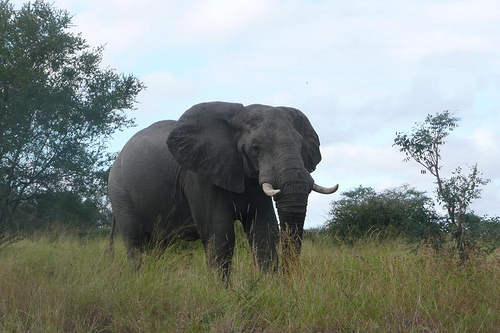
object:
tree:
[391, 108, 475, 265]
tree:
[0, 0, 149, 250]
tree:
[465, 212, 499, 255]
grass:
[412, 261, 477, 327]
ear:
[164, 100, 247, 194]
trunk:
[270, 144, 315, 272]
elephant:
[104, 100, 339, 290]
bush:
[316, 181, 449, 248]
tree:
[430, 162, 499, 263]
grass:
[133, 241, 203, 290]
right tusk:
[261, 182, 281, 197]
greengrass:
[40, 264, 437, 312]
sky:
[0, 0, 499, 232]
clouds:
[387, 0, 499, 88]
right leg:
[200, 207, 237, 288]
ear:
[273, 106, 321, 175]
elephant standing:
[99, 101, 339, 290]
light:
[328, 139, 391, 161]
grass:
[362, 207, 435, 263]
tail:
[108, 204, 117, 253]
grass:
[2, 252, 65, 315]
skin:
[135, 138, 216, 200]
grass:
[0, 223, 87, 264]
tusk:
[312, 182, 340, 195]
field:
[0, 0, 499, 332]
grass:
[0, 225, 499, 331]